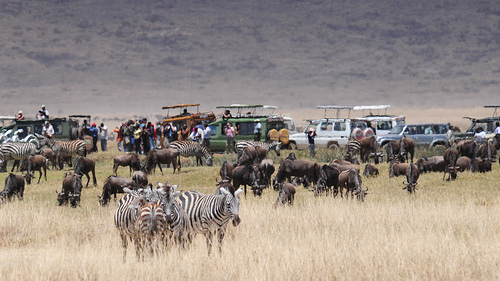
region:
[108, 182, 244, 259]
three zebras standing together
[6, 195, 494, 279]
tall brown grass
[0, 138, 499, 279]
animals in a field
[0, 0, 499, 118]
hillside in the background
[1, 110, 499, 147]
parked vehicles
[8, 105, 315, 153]
people watching the animals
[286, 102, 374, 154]
white truck with carrying racks on top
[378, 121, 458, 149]
silver colored vehicle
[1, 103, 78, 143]
person on top of a vehicle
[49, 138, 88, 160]
a brown and white striped zebra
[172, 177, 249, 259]
a zebra in a field of grass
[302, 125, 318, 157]
a person wearing a hat looking at wild animals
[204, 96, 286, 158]
a green safari vehicle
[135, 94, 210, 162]
an orange safari vehicle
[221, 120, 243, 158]
a person in a pink shirt photographing animals in the wild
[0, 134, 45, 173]
a zebra congregating in a herd of other wild animals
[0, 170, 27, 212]
a brown animal grazing on grass in the wild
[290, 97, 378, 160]
a white safari vehicle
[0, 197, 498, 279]
a field of prairie grasses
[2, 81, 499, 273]
a group of people watching animals while on safari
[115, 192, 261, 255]
Group of Zebras Standing Solitary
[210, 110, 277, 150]
Green Vehicle In Background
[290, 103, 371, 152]
White Car In Background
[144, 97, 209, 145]
Orange Car In Background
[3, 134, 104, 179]
Mixed group of animals together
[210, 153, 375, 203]
Herd of Cattle Eating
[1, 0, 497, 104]
Vast Empty Plains In Background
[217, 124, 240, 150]
Woman in Pink Shirt Black Pants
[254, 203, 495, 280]
Over grown high grass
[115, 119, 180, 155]
Group of Spectators Watching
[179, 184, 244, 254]
a standing black and white zebra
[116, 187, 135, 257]
a standing black and white zebra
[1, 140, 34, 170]
a standing black and white zebra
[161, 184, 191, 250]
a standing black and white zebra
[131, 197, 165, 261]
a standing brown and white zebra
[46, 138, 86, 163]
a standing brown and white zebra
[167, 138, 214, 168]
a standing brown and white zebra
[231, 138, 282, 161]
a standing black and white zebra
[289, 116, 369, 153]
a parked silver SUV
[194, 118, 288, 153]
a parked green truck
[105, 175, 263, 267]
a group of zebras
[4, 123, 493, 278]
several animals in the grass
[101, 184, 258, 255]
black and white zebras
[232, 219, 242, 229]
black snout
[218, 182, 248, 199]
two ears sticking out of the head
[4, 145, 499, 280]
long yellow grass on the ground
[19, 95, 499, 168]
row of cars driving through the grass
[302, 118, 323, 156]
person standing in the grass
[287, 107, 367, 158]
white vehicle in the line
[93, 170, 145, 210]
animal grazing in the grass